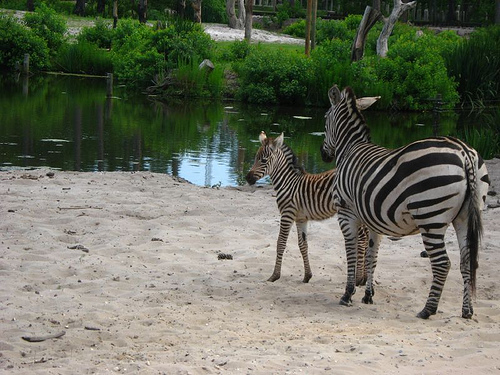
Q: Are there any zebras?
A: Yes, there is a zebra.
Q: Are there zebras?
A: Yes, there is a zebra.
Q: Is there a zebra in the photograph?
A: Yes, there is a zebra.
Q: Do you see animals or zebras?
A: Yes, there is a zebra.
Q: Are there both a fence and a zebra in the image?
A: No, there is a zebra but no fences.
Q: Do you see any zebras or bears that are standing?
A: Yes, the zebra is standing.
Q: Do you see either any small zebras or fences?
A: Yes, there is a small zebra.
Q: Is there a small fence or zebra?
A: Yes, there is a small zebra.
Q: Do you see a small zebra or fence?
A: Yes, there is a small zebra.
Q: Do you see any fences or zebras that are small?
A: Yes, the zebra is small.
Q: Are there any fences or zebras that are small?
A: Yes, the zebra is small.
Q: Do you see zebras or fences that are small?
A: Yes, the zebra is small.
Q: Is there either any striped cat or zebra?
A: Yes, there is a striped zebra.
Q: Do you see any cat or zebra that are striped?
A: Yes, the zebra is striped.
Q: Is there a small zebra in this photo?
A: Yes, there is a small zebra.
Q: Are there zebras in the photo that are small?
A: Yes, there is a zebra that is small.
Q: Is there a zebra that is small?
A: Yes, there is a zebra that is small.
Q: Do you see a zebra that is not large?
A: Yes, there is a small zebra.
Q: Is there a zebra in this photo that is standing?
A: Yes, there is a zebra that is standing.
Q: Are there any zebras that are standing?
A: Yes, there is a zebra that is standing.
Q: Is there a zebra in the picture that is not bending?
A: Yes, there is a zebra that is standing.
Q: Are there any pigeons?
A: No, there are no pigeons.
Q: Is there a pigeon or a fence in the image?
A: No, there are no pigeons or fences.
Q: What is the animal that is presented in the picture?
A: The animal is a zebra.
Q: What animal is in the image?
A: The animal is a zebra.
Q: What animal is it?
A: The animal is a zebra.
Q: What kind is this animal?
A: This is a zebra.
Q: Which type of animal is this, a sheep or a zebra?
A: This is a zebra.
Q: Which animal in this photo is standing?
A: The animal is a zebra.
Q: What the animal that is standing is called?
A: The animal is a zebra.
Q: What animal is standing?
A: The animal is a zebra.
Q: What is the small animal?
A: The animal is a zebra.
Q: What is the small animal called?
A: The animal is a zebra.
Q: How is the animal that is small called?
A: The animal is a zebra.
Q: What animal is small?
A: The animal is a zebra.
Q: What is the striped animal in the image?
A: The animal is a zebra.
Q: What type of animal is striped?
A: The animal is a zebra.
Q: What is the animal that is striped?
A: The animal is a zebra.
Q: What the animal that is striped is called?
A: The animal is a zebra.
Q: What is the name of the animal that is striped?
A: The animal is a zebra.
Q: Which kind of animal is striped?
A: The animal is a zebra.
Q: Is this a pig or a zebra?
A: This is a zebra.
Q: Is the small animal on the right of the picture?
A: Yes, the zebra is on the right of the image.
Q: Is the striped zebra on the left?
A: No, the zebra is on the right of the image.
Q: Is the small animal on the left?
A: No, the zebra is on the right of the image.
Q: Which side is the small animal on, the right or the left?
A: The zebra is on the right of the image.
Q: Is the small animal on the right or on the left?
A: The zebra is on the right of the image.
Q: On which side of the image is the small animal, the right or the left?
A: The zebra is on the right of the image.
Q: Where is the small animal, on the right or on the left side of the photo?
A: The zebra is on the right of the image.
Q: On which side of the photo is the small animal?
A: The zebra is on the right of the image.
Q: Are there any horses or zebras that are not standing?
A: No, there is a zebra but it is standing.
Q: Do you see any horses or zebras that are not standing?
A: No, there is a zebra but it is standing.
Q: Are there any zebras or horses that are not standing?
A: No, there is a zebra but it is standing.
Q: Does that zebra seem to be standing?
A: Yes, the zebra is standing.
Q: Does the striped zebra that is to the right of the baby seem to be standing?
A: Yes, the zebra is standing.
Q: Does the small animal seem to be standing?
A: Yes, the zebra is standing.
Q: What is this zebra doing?
A: The zebra is standing.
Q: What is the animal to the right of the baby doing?
A: The zebra is standing.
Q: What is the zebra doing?
A: The zebra is standing.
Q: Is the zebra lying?
A: No, the zebra is standing.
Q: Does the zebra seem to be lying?
A: No, the zebra is standing.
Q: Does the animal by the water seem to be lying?
A: No, the zebra is standing.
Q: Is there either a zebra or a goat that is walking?
A: No, there is a zebra but it is standing.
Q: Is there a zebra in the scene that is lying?
A: No, there is a zebra but it is standing.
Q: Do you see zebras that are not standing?
A: No, there is a zebra but it is standing.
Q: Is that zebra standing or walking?
A: The zebra is standing.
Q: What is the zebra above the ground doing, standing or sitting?
A: The zebra is standing.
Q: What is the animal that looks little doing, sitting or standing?
A: The zebra is standing.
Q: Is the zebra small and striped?
A: Yes, the zebra is small and striped.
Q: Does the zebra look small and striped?
A: Yes, the zebra is small and striped.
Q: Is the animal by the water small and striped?
A: Yes, the zebra is small and striped.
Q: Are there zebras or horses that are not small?
A: No, there is a zebra but it is small.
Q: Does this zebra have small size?
A: Yes, the zebra is small.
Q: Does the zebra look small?
A: Yes, the zebra is small.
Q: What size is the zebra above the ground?
A: The zebra is small.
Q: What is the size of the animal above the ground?
A: The zebra is small.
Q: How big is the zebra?
A: The zebra is small.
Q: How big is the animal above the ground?
A: The zebra is small.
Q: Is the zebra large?
A: No, the zebra is small.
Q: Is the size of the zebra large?
A: No, the zebra is small.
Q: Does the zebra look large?
A: No, the zebra is small.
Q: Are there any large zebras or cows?
A: No, there is a zebra but it is small.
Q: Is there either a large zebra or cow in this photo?
A: No, there is a zebra but it is small.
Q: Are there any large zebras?
A: No, there is a zebra but it is small.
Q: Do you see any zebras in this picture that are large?
A: No, there is a zebra but it is small.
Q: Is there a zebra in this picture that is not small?
A: No, there is a zebra but it is small.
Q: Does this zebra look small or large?
A: The zebra is small.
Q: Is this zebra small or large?
A: The zebra is small.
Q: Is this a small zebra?
A: Yes, this is a small zebra.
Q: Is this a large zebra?
A: No, this is a small zebra.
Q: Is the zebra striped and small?
A: Yes, the zebra is striped and small.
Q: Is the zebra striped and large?
A: No, the zebra is striped but small.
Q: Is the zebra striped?
A: Yes, the zebra is striped.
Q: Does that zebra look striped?
A: Yes, the zebra is striped.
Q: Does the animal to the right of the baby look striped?
A: Yes, the zebra is striped.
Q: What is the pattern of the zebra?
A: The zebra is striped.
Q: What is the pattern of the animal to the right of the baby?
A: The zebra is striped.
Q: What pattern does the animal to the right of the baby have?
A: The zebra has striped pattern.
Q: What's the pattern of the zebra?
A: The zebra is striped.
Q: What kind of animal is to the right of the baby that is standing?
A: The animal is a zebra.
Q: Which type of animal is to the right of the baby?
A: The animal is a zebra.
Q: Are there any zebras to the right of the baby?
A: Yes, there is a zebra to the right of the baby.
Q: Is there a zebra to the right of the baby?
A: Yes, there is a zebra to the right of the baby.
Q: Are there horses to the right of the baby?
A: No, there is a zebra to the right of the baby.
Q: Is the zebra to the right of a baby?
A: Yes, the zebra is to the right of a baby.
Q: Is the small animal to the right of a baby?
A: Yes, the zebra is to the right of a baby.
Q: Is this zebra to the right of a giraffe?
A: No, the zebra is to the right of a baby.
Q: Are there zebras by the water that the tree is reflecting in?
A: Yes, there is a zebra by the water.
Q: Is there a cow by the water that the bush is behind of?
A: No, there is a zebra by the water.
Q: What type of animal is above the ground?
A: The animal is a zebra.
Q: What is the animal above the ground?
A: The animal is a zebra.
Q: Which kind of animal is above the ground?
A: The animal is a zebra.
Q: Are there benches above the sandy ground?
A: No, there is a zebra above the ground.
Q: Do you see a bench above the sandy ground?
A: No, there is a zebra above the ground.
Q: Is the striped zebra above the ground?
A: Yes, the zebra is above the ground.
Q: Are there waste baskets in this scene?
A: No, there are no waste baskets.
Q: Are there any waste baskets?
A: No, there are no waste baskets.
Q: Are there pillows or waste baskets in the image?
A: No, there are no waste baskets or pillows.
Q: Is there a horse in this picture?
A: No, there are no horses.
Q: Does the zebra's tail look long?
A: Yes, the tail is long.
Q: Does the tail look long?
A: Yes, the tail is long.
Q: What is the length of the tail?
A: The tail is long.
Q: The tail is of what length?
A: The tail is long.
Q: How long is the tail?
A: The tail is long.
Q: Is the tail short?
A: No, the tail is long.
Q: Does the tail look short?
A: No, the tail is long.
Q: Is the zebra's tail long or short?
A: The tail is long.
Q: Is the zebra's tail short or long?
A: The tail is long.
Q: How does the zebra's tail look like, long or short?
A: The tail is long.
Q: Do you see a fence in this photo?
A: No, there are no fences.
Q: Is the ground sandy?
A: Yes, the ground is sandy.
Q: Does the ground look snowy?
A: No, the ground is sandy.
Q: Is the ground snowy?
A: No, the ground is sandy.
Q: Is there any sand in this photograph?
A: Yes, there is sand.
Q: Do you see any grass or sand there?
A: Yes, there is sand.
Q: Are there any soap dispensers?
A: No, there are no soap dispensers.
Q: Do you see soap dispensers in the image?
A: No, there are no soap dispensers.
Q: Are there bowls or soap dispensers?
A: No, there are no soap dispensers or bowls.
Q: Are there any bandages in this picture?
A: No, there are no bandages.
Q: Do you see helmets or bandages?
A: No, there are no bandages or helmets.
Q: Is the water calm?
A: Yes, the water is calm.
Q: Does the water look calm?
A: Yes, the water is calm.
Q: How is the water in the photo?
A: The water is calm.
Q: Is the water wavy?
A: No, the water is calm.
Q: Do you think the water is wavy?
A: No, the water is calm.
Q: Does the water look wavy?
A: No, the water is calm.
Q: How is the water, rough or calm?
A: The water is calm.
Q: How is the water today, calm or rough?
A: The water is calm.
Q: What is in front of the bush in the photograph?
A: The water is in front of the bush.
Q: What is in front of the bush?
A: The water is in front of the bush.